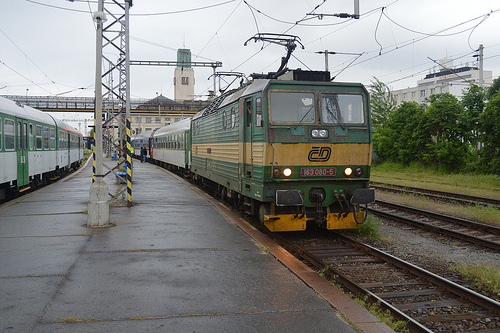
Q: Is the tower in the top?
A: Yes, the tower is in the top of the image.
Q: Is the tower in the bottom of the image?
A: No, the tower is in the top of the image.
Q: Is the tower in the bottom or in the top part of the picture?
A: The tower is in the top of the image.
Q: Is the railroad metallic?
A: Yes, the railroad is metallic.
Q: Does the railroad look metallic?
A: Yes, the railroad is metallic.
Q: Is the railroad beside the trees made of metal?
A: Yes, the railroad is made of metal.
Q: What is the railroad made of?
A: The railroad is made of metal.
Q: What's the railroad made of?
A: The railroad is made of metal.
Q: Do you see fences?
A: No, there are no fences.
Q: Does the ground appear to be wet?
A: Yes, the ground is wet.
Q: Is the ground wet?
A: Yes, the ground is wet.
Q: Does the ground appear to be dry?
A: No, the ground is wet.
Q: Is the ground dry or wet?
A: The ground is wet.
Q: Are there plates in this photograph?
A: Yes, there is a plate.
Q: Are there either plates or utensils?
A: Yes, there is a plate.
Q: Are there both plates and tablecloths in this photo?
A: No, there is a plate but no tablecloths.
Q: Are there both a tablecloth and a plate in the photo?
A: No, there is a plate but no tablecloths.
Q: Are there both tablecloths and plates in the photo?
A: No, there is a plate but no tablecloths.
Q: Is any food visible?
A: No, there is no food.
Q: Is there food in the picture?
A: No, there is no food.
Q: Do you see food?
A: No, there is no food.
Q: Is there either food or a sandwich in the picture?
A: No, there are no food or sandwiches.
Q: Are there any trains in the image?
A: Yes, there is a train.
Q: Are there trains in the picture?
A: Yes, there is a train.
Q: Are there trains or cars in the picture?
A: Yes, there is a train.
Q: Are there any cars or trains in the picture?
A: Yes, there is a train.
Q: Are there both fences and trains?
A: No, there is a train but no fences.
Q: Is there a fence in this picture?
A: No, there are no fences.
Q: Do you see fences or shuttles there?
A: No, there are no fences or shuttles.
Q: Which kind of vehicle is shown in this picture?
A: The vehicle is a train.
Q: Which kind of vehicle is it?
A: The vehicle is a train.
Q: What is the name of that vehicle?
A: This is a train.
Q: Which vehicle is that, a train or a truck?
A: This is a train.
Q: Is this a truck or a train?
A: This is a train.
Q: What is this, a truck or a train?
A: This is a train.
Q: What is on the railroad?
A: The train is on the railroad.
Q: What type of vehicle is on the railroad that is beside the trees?
A: The vehicle is a train.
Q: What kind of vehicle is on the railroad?
A: The vehicle is a train.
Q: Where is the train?
A: The train is on the railroad.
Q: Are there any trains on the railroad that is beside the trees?
A: Yes, there is a train on the railroad.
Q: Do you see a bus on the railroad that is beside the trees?
A: No, there is a train on the railroad.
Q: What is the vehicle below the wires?
A: The vehicle is a train.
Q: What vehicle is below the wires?
A: The vehicle is a train.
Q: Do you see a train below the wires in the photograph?
A: Yes, there is a train below the wires.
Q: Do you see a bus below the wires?
A: No, there is a train below the wires.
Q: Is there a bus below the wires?
A: No, there is a train below the wires.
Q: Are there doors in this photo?
A: Yes, there is a door.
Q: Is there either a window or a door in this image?
A: Yes, there is a door.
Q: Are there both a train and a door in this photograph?
A: Yes, there are both a door and a train.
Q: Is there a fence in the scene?
A: No, there are no fences.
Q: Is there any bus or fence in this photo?
A: No, there are no fences or buses.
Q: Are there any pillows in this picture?
A: No, there are no pillows.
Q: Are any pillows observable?
A: No, there are no pillows.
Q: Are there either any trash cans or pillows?
A: No, there are no pillows or trash cans.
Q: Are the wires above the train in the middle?
A: Yes, the wires are above the train.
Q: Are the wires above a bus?
A: No, the wires are above the train.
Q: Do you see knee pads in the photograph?
A: No, there are no knee pads.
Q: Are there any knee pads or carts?
A: No, there are no knee pads or carts.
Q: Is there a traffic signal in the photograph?
A: No, there are no traffic lights.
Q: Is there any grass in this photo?
A: Yes, there is grass.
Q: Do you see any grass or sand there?
A: Yes, there is grass.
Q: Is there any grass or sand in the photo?
A: Yes, there is grass.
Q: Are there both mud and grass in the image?
A: No, there is grass but no mud.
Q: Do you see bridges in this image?
A: Yes, there is a bridge.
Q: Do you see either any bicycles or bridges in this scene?
A: Yes, there is a bridge.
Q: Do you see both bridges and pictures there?
A: No, there is a bridge but no pictures.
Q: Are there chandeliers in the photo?
A: No, there are no chandeliers.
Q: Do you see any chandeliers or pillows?
A: No, there are no chandeliers or pillows.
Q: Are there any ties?
A: Yes, there is a tie.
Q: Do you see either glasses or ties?
A: Yes, there is a tie.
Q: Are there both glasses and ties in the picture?
A: No, there is a tie but no glasses.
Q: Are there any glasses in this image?
A: No, there are no glasses.